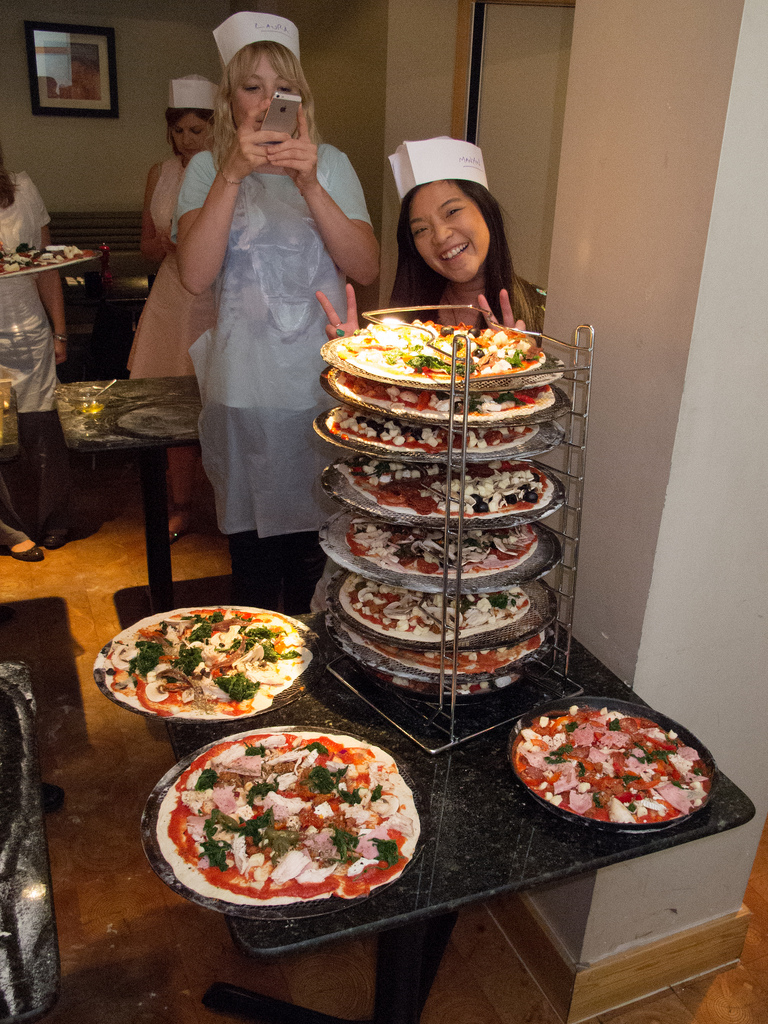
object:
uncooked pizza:
[99, 594, 292, 704]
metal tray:
[89, 635, 313, 723]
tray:
[531, 681, 729, 842]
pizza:
[336, 336, 558, 397]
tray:
[336, 336, 551, 397]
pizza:
[317, 373, 560, 438]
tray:
[317, 373, 560, 438]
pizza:
[323, 411, 556, 474]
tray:
[323, 411, 556, 474]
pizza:
[328, 466, 558, 526]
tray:
[328, 466, 558, 526]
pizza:
[333, 521, 568, 590]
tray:
[333, 521, 568, 590]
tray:
[333, 578, 555, 654]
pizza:
[365, 644, 598, 698]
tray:
[365, 644, 598, 698]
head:
[378, 137, 506, 291]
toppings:
[213, 761, 373, 859]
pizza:
[184, 758, 397, 876]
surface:
[184, 599, 496, 876]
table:
[429, 749, 513, 891]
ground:
[121, 904, 216, 988]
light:
[48, 539, 94, 927]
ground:
[66, 724, 128, 837]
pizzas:
[327, 323, 559, 736]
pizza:
[500, 692, 709, 829]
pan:
[516, 698, 710, 827]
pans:
[317, 317, 580, 707]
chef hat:
[384, 132, 499, 201]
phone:
[261, 87, 311, 166]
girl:
[206, 25, 340, 176]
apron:
[213, 184, 311, 419]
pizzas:
[313, 284, 641, 835]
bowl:
[0, 651, 37, 883]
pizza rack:
[311, 306, 597, 686]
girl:
[379, 131, 528, 295]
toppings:
[162, 625, 265, 686]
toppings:
[575, 731, 662, 792]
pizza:
[350, 588, 531, 632]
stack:
[318, 293, 573, 739]